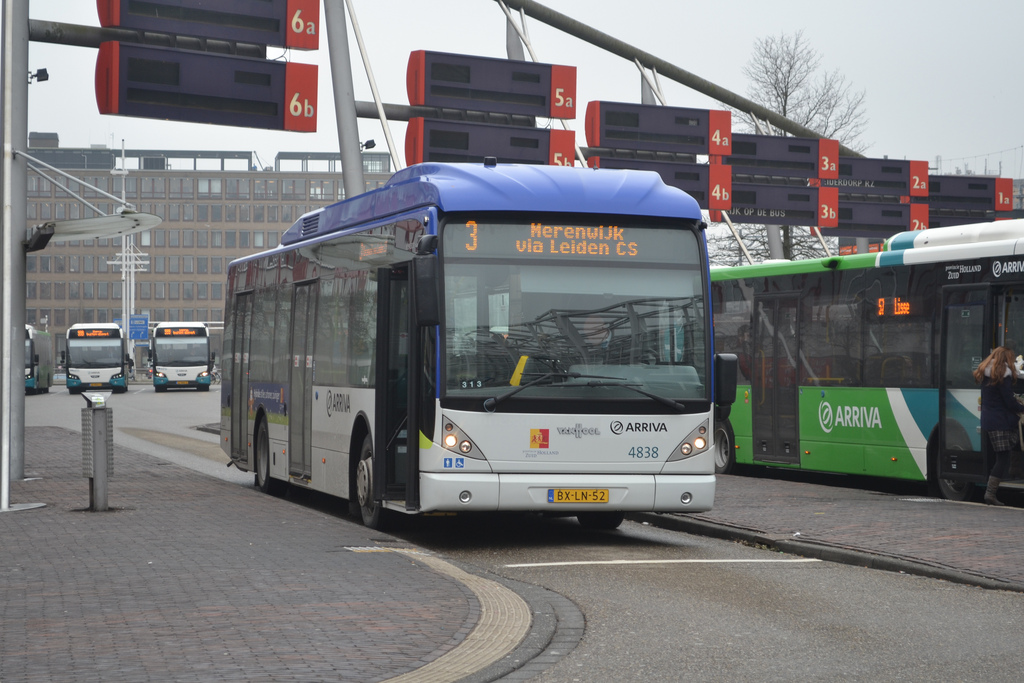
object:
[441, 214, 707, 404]
glass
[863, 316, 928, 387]
glass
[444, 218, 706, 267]
display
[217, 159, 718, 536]
bus